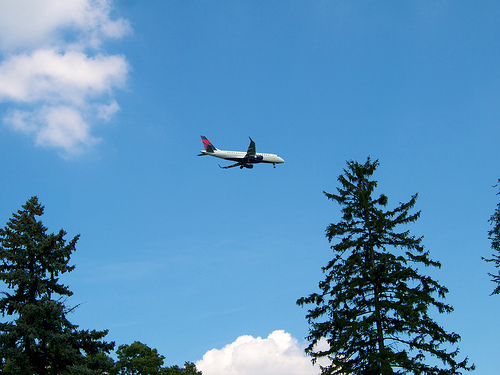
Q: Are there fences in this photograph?
A: No, there are no fences.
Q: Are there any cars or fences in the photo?
A: No, there are no fences or cars.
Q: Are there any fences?
A: No, there are no fences.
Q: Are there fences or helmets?
A: No, there are no fences or helmets.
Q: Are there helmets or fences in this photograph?
A: No, there are no fences or helmets.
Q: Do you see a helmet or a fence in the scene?
A: No, there are no fences or helmets.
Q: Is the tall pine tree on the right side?
A: Yes, the pine is on the right of the image.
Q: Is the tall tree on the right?
A: Yes, the pine is on the right of the image.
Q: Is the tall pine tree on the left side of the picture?
A: No, the pine is on the right of the image.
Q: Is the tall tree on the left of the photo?
A: No, the pine is on the right of the image.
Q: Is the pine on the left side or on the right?
A: The pine is on the right of the image.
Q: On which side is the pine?
A: The pine is on the right of the image.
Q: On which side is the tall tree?
A: The pine is on the right of the image.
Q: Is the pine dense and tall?
A: No, the pine is tall but sparse.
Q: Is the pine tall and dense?
A: No, the pine is tall but sparse.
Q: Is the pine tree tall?
A: Yes, the pine tree is tall.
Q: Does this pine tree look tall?
A: Yes, the pine tree is tall.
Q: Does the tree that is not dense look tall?
A: Yes, the pine tree is tall.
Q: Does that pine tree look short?
A: No, the pine tree is tall.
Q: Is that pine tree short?
A: No, the pine tree is tall.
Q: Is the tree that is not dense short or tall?
A: The pine tree is tall.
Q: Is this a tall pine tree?
A: Yes, this is a tall pine tree.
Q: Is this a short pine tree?
A: No, this is a tall pine tree.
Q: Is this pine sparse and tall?
A: Yes, the pine is sparse and tall.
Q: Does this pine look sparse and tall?
A: Yes, the pine is sparse and tall.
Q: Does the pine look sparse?
A: Yes, the pine is sparse.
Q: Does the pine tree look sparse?
A: Yes, the pine tree is sparse.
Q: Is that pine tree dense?
A: No, the pine tree is sparse.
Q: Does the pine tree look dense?
A: No, the pine tree is sparse.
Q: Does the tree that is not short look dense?
A: No, the pine tree is sparse.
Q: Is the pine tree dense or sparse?
A: The pine tree is sparse.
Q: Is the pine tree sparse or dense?
A: The pine tree is sparse.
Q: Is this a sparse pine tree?
A: Yes, this is a sparse pine tree.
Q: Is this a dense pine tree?
A: No, this is a sparse pine tree.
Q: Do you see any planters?
A: No, there are no planters.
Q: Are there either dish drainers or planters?
A: No, there are no planters or dish drainers.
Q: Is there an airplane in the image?
A: Yes, there is an airplane.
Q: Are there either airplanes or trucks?
A: Yes, there is an airplane.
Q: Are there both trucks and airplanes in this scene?
A: No, there is an airplane but no trucks.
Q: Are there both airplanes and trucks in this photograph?
A: No, there is an airplane but no trucks.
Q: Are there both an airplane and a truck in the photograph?
A: No, there is an airplane but no trucks.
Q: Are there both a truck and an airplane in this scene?
A: No, there is an airplane but no trucks.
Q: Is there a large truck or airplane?
A: Yes, there is a large airplane.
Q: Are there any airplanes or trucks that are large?
A: Yes, the airplane is large.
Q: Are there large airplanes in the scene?
A: Yes, there is a large airplane.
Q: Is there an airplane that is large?
A: Yes, there is an airplane that is large.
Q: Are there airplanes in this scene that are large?
A: Yes, there is an airplane that is large.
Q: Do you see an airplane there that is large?
A: Yes, there is an airplane that is large.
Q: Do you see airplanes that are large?
A: Yes, there is an airplane that is large.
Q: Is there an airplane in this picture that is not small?
A: Yes, there is a large airplane.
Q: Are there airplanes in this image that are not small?
A: Yes, there is a large airplane.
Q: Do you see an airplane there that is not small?
A: Yes, there is a large airplane.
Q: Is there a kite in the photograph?
A: No, there are no kites.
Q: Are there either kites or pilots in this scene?
A: No, there are no kites or pilots.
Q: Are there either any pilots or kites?
A: No, there are no kites or pilots.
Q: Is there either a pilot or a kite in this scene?
A: No, there are no kites or pilots.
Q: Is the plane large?
A: Yes, the plane is large.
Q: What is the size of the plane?
A: The plane is large.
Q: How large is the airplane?
A: The airplane is large.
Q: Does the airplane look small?
A: No, the airplane is large.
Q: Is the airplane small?
A: No, the airplane is large.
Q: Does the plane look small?
A: No, the plane is large.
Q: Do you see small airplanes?
A: No, there is an airplane but it is large.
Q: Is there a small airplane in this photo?
A: No, there is an airplane but it is large.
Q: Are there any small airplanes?
A: No, there is an airplane but it is large.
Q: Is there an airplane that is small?
A: No, there is an airplane but it is large.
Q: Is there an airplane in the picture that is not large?
A: No, there is an airplane but it is large.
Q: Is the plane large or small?
A: The plane is large.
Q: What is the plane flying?
A: The plane is flying the trees.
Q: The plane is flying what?
A: The plane is flying the trees.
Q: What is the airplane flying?
A: The plane is flying the trees.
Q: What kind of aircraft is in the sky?
A: The aircraft is an airplane.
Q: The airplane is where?
A: The airplane is in the sky.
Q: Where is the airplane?
A: The airplane is in the sky.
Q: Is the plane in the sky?
A: Yes, the plane is in the sky.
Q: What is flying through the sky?
A: The airplane is flying through the sky.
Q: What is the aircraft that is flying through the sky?
A: The aircraft is an airplane.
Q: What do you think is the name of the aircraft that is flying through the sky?
A: The aircraft is an airplane.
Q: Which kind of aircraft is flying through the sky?
A: The aircraft is an airplane.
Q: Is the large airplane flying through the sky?
A: Yes, the airplane is flying through the sky.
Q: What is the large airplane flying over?
A: The plane is flying over the trees.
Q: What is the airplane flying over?
A: The plane is flying over the trees.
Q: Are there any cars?
A: No, there are no cars.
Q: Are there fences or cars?
A: No, there are no cars or fences.